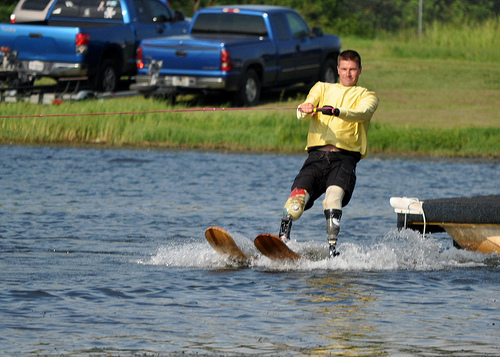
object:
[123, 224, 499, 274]
waves water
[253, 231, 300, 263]
ski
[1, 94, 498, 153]
grass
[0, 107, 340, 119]
rope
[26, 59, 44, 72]
license plate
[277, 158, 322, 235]
prosthetic leg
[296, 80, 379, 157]
top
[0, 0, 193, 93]
blue truck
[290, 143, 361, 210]
shorts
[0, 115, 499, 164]
bank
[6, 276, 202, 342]
water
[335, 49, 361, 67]
hair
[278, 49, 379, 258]
guy's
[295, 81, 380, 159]
shirt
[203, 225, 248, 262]
ski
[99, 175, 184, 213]
water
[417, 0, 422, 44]
pole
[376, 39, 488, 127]
grass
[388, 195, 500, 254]
dock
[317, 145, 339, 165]
drawstring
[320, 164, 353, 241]
legs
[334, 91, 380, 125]
prosthetic arm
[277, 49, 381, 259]
guy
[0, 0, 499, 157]
field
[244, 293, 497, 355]
water